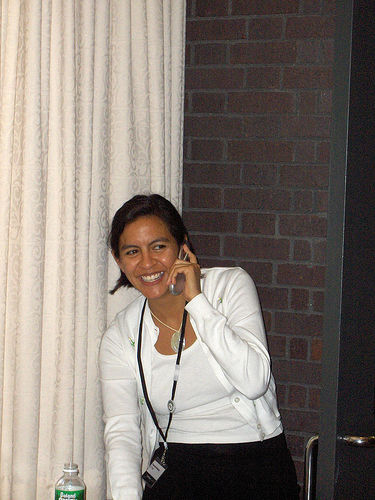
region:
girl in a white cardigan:
[85, 190, 286, 499]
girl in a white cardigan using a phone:
[90, 186, 303, 499]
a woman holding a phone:
[96, 186, 301, 499]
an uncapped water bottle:
[49, 458, 90, 499]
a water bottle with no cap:
[48, 458, 87, 498]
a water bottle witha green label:
[48, 459, 92, 499]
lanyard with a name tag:
[138, 286, 201, 487]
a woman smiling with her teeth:
[99, 188, 299, 498]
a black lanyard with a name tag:
[133, 286, 192, 491]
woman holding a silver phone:
[99, 182, 292, 499]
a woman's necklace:
[143, 301, 192, 352]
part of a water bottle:
[56, 460, 87, 499]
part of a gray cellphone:
[167, 245, 189, 303]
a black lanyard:
[135, 288, 195, 486]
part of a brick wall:
[188, 0, 331, 262]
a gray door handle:
[303, 430, 327, 498]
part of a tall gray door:
[302, 0, 372, 499]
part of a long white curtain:
[0, 0, 195, 498]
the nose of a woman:
[138, 247, 154, 270]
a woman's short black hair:
[102, 195, 191, 295]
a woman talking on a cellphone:
[96, 196, 301, 497]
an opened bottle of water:
[43, 460, 99, 497]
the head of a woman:
[97, 186, 208, 322]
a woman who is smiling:
[98, 188, 207, 308]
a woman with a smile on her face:
[91, 196, 213, 298]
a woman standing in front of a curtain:
[2, 152, 181, 393]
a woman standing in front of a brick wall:
[120, 160, 331, 402]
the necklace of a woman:
[151, 307, 199, 366]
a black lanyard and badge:
[124, 305, 195, 490]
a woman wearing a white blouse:
[86, 170, 291, 450]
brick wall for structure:
[188, 4, 325, 227]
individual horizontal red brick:
[226, 138, 295, 158]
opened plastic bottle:
[53, 459, 87, 498]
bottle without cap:
[53, 461, 89, 498]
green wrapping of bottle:
[53, 488, 85, 498]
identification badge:
[140, 453, 167, 485]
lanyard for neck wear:
[137, 299, 186, 483]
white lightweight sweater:
[200, 274, 276, 436]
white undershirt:
[145, 347, 248, 438]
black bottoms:
[149, 441, 296, 498]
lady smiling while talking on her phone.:
[93, 187, 289, 494]